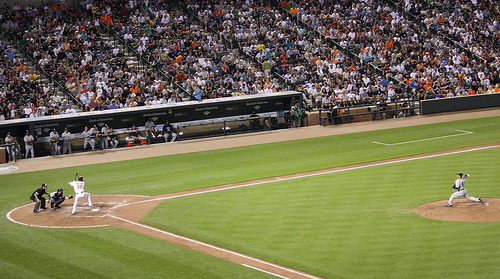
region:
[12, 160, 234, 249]
People on the field.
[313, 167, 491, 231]
Pitcher in the field.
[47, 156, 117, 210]
Batter on the field.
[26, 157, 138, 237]
People playing baseball.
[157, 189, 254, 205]
Lines on the field.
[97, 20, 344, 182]
Crowds in the stand.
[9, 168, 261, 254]
Dirt on the pitcher's mound.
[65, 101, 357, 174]
People on the sidelines.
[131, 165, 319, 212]
Grass on the field.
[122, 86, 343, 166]
Dugout on the field.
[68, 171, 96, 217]
he prepares to hit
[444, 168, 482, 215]
the picher about to throw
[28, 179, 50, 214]
the ump crouches over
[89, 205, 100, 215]
the home plate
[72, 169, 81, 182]
a black baseball bat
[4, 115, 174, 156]
the team in the dugout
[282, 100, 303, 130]
the man works the camera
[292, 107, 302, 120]
a green tee shirt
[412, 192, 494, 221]
the dirt on the pitchers mound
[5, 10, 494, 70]
fans in the stadium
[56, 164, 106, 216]
Batter standing at home plate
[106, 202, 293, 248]
White chalk on the field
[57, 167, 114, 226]
Baseball player is wearing a white uniform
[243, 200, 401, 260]
The field grass is cut short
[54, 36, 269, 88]
Spectators sitting in the stands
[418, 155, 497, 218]
The pitcher is throwing a ball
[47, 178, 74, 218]
Catcher behind the batter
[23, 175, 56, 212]
Umpire is standing behind the catcher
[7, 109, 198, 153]
Players sitting in the dugout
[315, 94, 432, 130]
Fence in front of spectators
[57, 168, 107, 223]
Batter has leg up.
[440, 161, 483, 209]
Pitcher about to throw the ball.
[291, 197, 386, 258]
The grass is green.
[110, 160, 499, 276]
Dirt around the diamond.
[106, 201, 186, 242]
White lines in the dirt.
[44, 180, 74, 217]
Catcher behind the batter.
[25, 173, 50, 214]
Umpire behind the catcher.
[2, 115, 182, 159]
Players watching the game.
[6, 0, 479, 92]
People in the stadium.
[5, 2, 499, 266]
Taken during a baseball game.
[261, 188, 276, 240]
the grass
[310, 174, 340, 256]
the grass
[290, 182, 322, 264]
the grass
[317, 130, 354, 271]
the grass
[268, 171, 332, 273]
the grass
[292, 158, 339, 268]
the grass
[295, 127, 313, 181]
the grass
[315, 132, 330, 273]
the grass